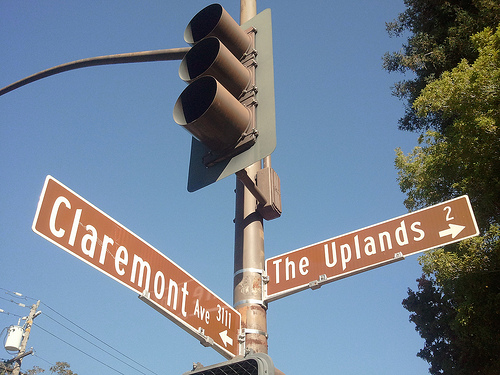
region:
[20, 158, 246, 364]
Claremont Ave street sign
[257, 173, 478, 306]
The Uplands street sign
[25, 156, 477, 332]
street signs for an intersection at a stop light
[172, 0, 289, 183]
stoplight at a street intersection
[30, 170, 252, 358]
brown street sign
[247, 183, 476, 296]
brown street sign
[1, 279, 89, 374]
electrical pole and wires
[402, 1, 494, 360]
tall green trees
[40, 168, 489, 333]
two street signs at an intersection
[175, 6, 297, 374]
metal stoplight mounted on a street sign pole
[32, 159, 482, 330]
The sign is brown.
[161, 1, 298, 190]
The street lamp is grey.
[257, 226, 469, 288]
The lettering is white.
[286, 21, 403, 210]
The sky is clear.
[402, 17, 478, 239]
The tree is leafy.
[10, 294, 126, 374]
The telephone lines are going across the sky.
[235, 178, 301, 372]
The pole is brown.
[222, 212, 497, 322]
The sign is hanging off the pole.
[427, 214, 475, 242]
THe arrow is white.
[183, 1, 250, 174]
The covers are brown.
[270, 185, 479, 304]
a street sign for "The Uplands"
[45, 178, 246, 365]
A street sign for "Claremont Ave"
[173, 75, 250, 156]
part of a traffic signal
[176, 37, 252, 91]
part of a traffic signal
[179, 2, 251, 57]
part of a traffic signal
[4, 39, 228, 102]
part of a street light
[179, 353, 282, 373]
part of a walking signal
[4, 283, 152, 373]
telephone lines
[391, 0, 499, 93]
green leaves on a tree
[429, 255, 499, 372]
green leaves on a tree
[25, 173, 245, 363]
brown street sign with white letters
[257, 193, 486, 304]
brown street sign with white letters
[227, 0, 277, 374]
metal light pole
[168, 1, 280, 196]
brown metal traffic light attached to light pole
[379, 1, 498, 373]
green tree near intersection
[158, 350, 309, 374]
pedestrian traffic light attached to metal light pole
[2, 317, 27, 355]
white metal cylindrical box attached to power lines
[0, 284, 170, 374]
power lines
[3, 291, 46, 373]
light gray wooden power line post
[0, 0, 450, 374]
medium blue sky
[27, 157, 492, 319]
Two street sign on the pole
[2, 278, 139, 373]
Overhead electric lines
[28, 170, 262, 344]
Brown and white street sign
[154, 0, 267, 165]
Traffic lights on the pole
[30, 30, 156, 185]
Clear sky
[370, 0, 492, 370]
Tall green tree on the right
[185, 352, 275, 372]
Pedestrian traffic signal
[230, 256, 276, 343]
Street sign fasteners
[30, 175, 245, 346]
Claremont Avenue sign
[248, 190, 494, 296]
The Uplands Sign